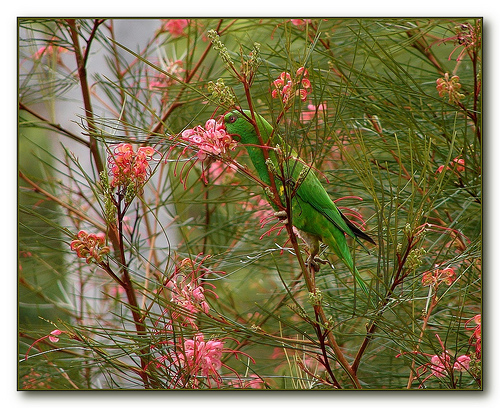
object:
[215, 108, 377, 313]
bird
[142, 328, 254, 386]
flowers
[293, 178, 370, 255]
feathers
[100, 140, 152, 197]
flower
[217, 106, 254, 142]
head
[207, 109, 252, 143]
face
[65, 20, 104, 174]
stick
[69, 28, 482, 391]
tree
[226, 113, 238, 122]
eye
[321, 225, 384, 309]
tail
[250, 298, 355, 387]
leaves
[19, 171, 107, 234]
stem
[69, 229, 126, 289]
branches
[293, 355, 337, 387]
branch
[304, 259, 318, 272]
claws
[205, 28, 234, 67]
buds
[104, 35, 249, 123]
twigs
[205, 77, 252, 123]
branch